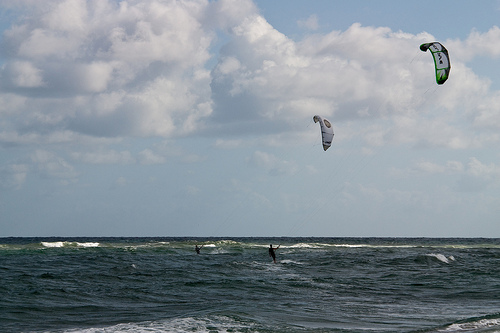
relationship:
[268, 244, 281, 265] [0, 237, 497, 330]
person skiing in ocean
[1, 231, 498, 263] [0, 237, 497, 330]
wave in ocean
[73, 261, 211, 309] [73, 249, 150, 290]
ripples in water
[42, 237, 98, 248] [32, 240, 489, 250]
caps of wave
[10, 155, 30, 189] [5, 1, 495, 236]
cloud in sky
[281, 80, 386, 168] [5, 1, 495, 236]
kite in sky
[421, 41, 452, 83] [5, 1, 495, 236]
sail in sky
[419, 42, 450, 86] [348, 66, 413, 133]
sail in sky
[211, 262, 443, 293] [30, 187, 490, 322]
wave in ocean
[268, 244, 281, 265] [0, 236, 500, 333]
person in ocean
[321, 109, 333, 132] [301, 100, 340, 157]
circle on sail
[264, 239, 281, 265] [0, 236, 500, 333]
person in ocean